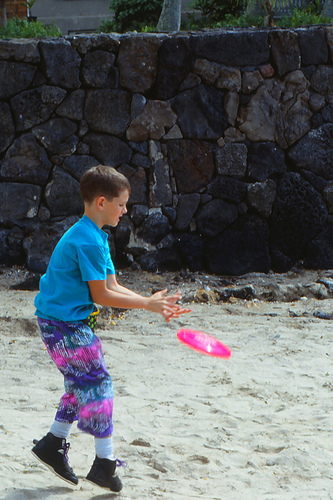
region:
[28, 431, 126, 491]
Black sneakers on boy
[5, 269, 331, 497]
White sand covered ground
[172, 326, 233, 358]
Pink frisbee in the air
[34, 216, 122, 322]
Blue shirt on boy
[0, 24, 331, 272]
Rock wall in background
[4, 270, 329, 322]
Rocks scattered on sandy ground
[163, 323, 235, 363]
round pink frisbee in the air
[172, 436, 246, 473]
footprints in the sand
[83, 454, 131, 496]
black high top sneakers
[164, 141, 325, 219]
rock cluster in the back ground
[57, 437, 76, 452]
laces on black sneakers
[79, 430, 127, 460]
edge of white socks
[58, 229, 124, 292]
sleeves on blue shirt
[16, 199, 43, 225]
white color on the rock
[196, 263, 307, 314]
stones on the sand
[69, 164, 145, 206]
boy's short hair cut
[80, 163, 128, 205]
the hair is brown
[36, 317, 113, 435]
purple and pink pants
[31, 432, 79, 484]
the shoe is black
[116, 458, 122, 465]
shoe lace is purple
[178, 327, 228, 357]
the frisbee is pink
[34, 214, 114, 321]
the shirt is blue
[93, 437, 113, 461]
the sock is white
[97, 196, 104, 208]
ear of a boy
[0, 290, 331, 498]
sand in the area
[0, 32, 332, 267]
wall made of stone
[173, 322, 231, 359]
bright pink frisbee in flight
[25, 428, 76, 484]
black tennis shoe with black tag off heel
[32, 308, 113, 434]
bright colorful mid shin pants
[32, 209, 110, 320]
medium blue shirt worn by boy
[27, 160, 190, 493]
boy jumping to catch frisbee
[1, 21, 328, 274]
handcrafted stone wall behind boy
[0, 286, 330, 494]
beige sandy ground of beach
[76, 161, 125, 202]
boy with short brown hair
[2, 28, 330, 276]
surface of stone wall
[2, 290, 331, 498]
sandy surface of beach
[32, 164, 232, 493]
boy reaching for frisbee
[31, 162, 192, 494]
Boy in blue shirt plays with pink frisbee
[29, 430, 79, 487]
Black tennis shoe on left foot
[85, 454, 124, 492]
black tennis shoe on right foot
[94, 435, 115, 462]
white tube socks on right foot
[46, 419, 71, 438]
white tube sock on left foot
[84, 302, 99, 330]
boy wear green and black pack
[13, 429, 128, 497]
a boy wearing shoes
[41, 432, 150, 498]
a boy waring black shoes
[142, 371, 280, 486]
an area of sand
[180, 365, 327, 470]
an area of sand on the beach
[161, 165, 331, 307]
a wall made of rock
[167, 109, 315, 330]
a rock structure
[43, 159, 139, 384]
a boy waring a shirt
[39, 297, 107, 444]
a boy wearing pants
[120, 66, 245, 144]
bricks on the tall wall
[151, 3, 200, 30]
tree trunk behind the wall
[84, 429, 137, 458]
chunky white socks on feet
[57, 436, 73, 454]
laces in black sneakers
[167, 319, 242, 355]
pink frisbee being thrown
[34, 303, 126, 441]
boy wearing multi colored pants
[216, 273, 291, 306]
rocks on the sand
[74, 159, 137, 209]
boy's short hair cut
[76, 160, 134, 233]
The head of a boy